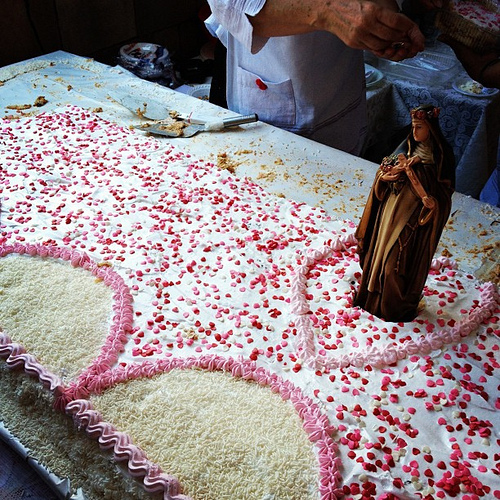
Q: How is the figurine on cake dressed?
A: In long robe.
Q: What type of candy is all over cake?
A: Sprinkles.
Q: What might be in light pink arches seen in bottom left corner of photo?
A: Coconut.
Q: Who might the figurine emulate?
A: Jesus christ.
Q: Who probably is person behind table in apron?
A: Baker.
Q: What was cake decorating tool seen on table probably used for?
A: Spreading frosting.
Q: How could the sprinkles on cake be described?
A: Red and pink.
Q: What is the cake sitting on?
A: Table.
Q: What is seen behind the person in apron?
A: Small table.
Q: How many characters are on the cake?
A: One.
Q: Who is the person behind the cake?
A: Baker.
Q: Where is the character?
A: On the cake.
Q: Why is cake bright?
A: Light.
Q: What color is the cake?
A: Pink, white, and red.